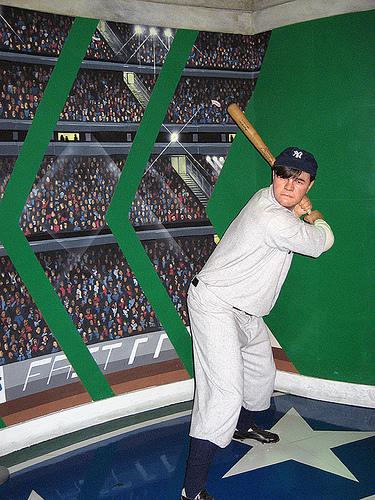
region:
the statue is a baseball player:
[226, 104, 316, 221]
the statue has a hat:
[279, 146, 319, 174]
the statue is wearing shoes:
[181, 425, 277, 498]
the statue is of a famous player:
[177, 103, 332, 496]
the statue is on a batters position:
[189, 102, 326, 498]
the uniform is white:
[185, 190, 333, 442]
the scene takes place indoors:
[2, 2, 370, 498]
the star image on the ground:
[220, 408, 373, 481]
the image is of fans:
[0, 4, 270, 368]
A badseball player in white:
[190, 132, 349, 493]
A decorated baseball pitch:
[81, 437, 172, 498]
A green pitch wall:
[296, 280, 372, 376]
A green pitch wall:
[269, 85, 373, 132]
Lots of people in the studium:
[48, 261, 128, 341]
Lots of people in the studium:
[2, 282, 55, 358]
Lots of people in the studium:
[147, 233, 199, 288]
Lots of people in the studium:
[46, 158, 114, 227]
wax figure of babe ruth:
[182, 156, 338, 498]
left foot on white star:
[240, 418, 355, 488]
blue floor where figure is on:
[71, 442, 178, 491]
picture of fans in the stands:
[9, 63, 187, 325]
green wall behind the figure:
[274, 29, 374, 154]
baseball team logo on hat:
[295, 149, 305, 165]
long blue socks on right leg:
[187, 434, 205, 488]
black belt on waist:
[190, 282, 220, 301]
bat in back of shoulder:
[227, 103, 337, 224]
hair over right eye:
[267, 168, 302, 180]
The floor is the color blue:
[54, 452, 191, 498]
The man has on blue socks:
[184, 436, 215, 484]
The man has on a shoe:
[234, 414, 280, 444]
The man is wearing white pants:
[172, 278, 283, 445]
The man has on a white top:
[196, 173, 337, 317]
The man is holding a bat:
[214, 99, 332, 227]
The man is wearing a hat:
[265, 133, 328, 181]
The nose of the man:
[282, 174, 296, 192]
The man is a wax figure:
[173, 103, 374, 498]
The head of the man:
[270, 144, 321, 209]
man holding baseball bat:
[177, 100, 333, 499]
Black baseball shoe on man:
[233, 423, 281, 441]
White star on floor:
[222, 405, 370, 484]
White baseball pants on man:
[180, 280, 276, 446]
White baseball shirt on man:
[191, 188, 335, 311]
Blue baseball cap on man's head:
[272, 145, 319, 173]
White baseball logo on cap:
[292, 149, 303, 159]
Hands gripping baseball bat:
[297, 197, 321, 220]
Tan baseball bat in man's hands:
[228, 104, 315, 218]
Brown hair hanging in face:
[274, 165, 301, 180]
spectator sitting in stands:
[4, 348, 15, 366]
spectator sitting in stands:
[8, 340, 16, 359]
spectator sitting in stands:
[16, 345, 26, 358]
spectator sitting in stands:
[23, 339, 33, 355]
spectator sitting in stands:
[31, 335, 37, 350]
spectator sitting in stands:
[34, 341, 48, 354]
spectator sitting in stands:
[11, 320, 19, 334]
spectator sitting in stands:
[61, 294, 71, 305]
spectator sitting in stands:
[76, 310, 85, 326]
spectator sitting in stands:
[103, 296, 113, 313]